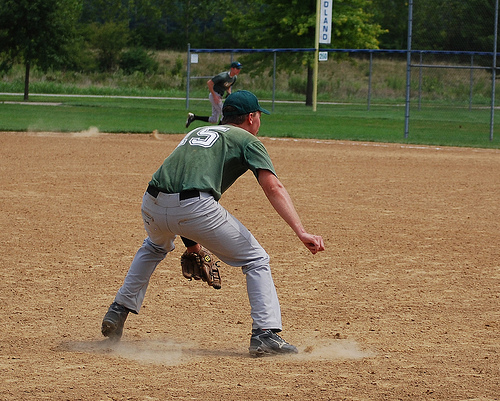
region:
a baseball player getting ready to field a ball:
[95, 86, 327, 362]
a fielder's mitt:
[179, 248, 224, 288]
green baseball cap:
[220, 87, 270, 116]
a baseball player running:
[183, 58, 243, 134]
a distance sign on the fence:
[317, 48, 332, 63]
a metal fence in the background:
[178, 23, 498, 144]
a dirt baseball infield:
[0, 123, 499, 399]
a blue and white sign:
[318, 0, 333, 46]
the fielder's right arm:
[252, 165, 327, 260]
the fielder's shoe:
[246, 325, 299, 360]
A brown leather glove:
[176, 242, 225, 295]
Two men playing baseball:
[96, 56, 330, 362]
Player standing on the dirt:
[88, 86, 329, 375]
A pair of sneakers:
[95, 299, 305, 362]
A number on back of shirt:
[176, 113, 233, 156]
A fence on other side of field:
[180, 37, 499, 142]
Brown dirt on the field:
[2, 125, 498, 398]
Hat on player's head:
[216, 86, 275, 139]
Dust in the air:
[80, 329, 373, 374]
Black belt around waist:
[139, 179, 218, 209]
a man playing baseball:
[40, 40, 456, 398]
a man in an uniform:
[27, 41, 432, 397]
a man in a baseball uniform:
[73, 22, 407, 387]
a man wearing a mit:
[129, 76, 461, 371]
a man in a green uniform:
[52, 53, 394, 399]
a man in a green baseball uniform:
[87, 101, 346, 382]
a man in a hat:
[104, 37, 331, 344]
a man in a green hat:
[130, 65, 319, 376]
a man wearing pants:
[125, 114, 279, 350]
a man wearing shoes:
[85, 115, 344, 391]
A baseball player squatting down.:
[92, 82, 324, 357]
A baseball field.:
[5, 90, 495, 395]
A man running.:
[180, 60, 237, 125]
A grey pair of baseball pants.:
[110, 185, 280, 330]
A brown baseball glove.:
[180, 245, 220, 285]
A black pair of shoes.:
[96, 301, 306, 356]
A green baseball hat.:
[222, 87, 270, 117]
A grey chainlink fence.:
[186, 47, 498, 139]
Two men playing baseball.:
[78, 39, 343, 371]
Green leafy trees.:
[0, 0, 499, 95]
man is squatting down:
[85, 73, 340, 363]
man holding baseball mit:
[182, 228, 221, 294]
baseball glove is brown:
[170, 243, 230, 294]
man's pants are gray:
[114, 168, 289, 329]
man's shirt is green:
[144, 110, 284, 205]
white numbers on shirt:
[163, 112, 238, 172]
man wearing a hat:
[214, 86, 271, 126]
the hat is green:
[214, 79, 276, 133]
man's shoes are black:
[84, 304, 311, 364]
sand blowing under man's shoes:
[81, 315, 363, 369]